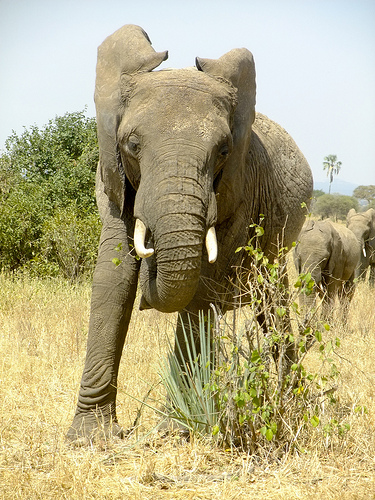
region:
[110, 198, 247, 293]
two white elephant tusks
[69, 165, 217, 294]
two white elephant tusks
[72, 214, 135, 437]
elephant's skin is wrinkled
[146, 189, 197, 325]
elephant's skin is wrinkled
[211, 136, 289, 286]
elephant's skin is wrinkled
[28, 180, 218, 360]
elephant's skin is wrinkled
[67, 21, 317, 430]
large gray elephant with white tusks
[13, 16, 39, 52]
white clouds in blue sky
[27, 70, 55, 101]
white clouds in blue sky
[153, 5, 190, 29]
white clouds in blue sky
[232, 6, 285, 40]
white clouds in blue sky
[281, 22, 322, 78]
white clouds in blue sky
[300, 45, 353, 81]
white clouds in blue sky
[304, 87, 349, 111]
white clouds in blue sky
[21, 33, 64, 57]
white clouds in blue sky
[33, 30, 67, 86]
white clouds in blue sky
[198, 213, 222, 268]
White tusk on elephant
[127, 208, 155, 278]
White tusk on elephant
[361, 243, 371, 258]
White tusk on elephant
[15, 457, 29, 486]
Small patch of grass in field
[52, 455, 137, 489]
Small patch of grass in field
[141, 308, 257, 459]
Small patch of grass in field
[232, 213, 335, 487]
Small patch of grass in field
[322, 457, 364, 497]
Small patch of grass in field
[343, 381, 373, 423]
Small patch of grass in field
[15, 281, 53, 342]
Small patch of grass in field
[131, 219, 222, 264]
a pair of ivory elephant tusks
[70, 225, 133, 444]
an elephants grey leg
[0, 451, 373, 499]
a patch of dead brown grass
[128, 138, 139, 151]
the eye of a elephant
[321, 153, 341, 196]
a very tall palm tree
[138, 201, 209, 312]
the trunk of an elephant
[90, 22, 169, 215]
an elephants ear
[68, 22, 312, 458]
an elephant eating leafs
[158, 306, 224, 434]
a spikey green plant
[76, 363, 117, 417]
a patch of wrinkled elephant skin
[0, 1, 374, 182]
blue in daytime sky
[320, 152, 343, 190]
leafes on palm tree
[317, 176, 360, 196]
hazy mountain on horizon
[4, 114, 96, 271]
green leaves on bush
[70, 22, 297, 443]
elephant standing in brush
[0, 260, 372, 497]
tall dried grass on ground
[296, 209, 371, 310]
two walking elephants in the rear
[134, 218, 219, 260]
two white ivory tusks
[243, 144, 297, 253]
wrinkles on elephant skin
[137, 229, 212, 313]
curled up elephant trunk